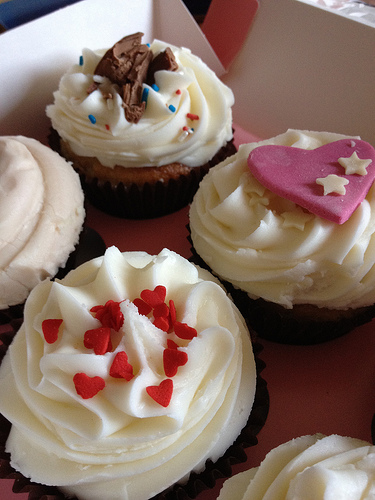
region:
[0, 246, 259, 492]
chocolate cupcake with red sprinkles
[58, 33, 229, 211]
a red cupcake with chocolate chunks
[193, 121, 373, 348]
a chocolate cupcake with a heart shaped cookie on it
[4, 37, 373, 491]
a box of personalized cupcakes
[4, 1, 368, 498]
a white box with snacks in it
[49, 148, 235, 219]
black paper wrapped around cake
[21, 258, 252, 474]
the frosting is white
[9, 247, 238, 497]
the frosting is white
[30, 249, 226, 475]
the frosting is white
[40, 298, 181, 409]
red heart-shaped sprinkle on the frosting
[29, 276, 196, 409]
red heart-shaped sprinkle on the frosting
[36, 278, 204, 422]
red heart-shaped sprinkle on the frosting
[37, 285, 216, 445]
red heart-shaped sprinkle on the frosting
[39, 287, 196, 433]
red heart-shaped sprinkle on the frosting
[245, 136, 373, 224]
a pink heart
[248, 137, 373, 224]
a pink heart with light pink stars on top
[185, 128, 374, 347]
a cup cake with a heart and stars on top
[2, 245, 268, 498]
a round cupcake with white icing and red hearts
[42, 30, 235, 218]
a cupcake with white icing and sprinkles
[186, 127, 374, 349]
a light brown cupcake with dark brown paper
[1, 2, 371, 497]
cupcakes in a cardboard box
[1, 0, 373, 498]
cardboard box is white and pink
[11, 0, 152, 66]
light reflecting on the cardboard box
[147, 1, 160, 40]
dark shadow in the corner of the box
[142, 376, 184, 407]
red topping on a cake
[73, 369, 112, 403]
red topping on a cake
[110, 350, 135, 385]
red topping on a cake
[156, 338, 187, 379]
red topping on a cake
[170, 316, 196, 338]
red topping on a cake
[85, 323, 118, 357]
red topping on a cake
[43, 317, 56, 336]
red topping on a cake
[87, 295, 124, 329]
red topping on a cake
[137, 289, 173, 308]
red topping on a cake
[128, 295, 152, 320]
red topping on a cake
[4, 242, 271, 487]
chocolate cupcake with red sprinkles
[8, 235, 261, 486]
swirled white icing on chocolate cupcake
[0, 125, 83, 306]
pink icingon chocolate cupcake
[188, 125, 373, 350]
white frosting on chocolate cupcake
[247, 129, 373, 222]
pink heart on white frosting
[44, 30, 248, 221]
chocolate cupcake with blue sprinkles and chocolate bits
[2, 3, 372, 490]
pink and white cardboard box containing cupcakes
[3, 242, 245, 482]
red heart sprinkles on white frosting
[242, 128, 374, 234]
pink sugar heart on chocolate cup cake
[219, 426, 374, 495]
edge of white frosting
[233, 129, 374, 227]
a pink heart-shaped topper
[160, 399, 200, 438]
cream is white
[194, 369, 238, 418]
cream on the cupcake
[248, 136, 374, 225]
two stars on a pink heart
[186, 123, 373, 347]
chocolate cupcake with white frosting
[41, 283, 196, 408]
red hearts on top of white frosting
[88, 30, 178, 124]
chocolate frosting in the middle of vanilla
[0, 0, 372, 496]
five cupcakes in a white box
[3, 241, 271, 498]
cupcake decorated with red hearts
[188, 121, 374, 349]
cupcake decorated with pink heart and white stars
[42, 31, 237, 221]
cupcake with sprinkles and frosting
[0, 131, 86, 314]
hardened white vanilla frosting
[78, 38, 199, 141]
red white and blue sprinkles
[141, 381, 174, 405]
A spinkle on a cupcake.